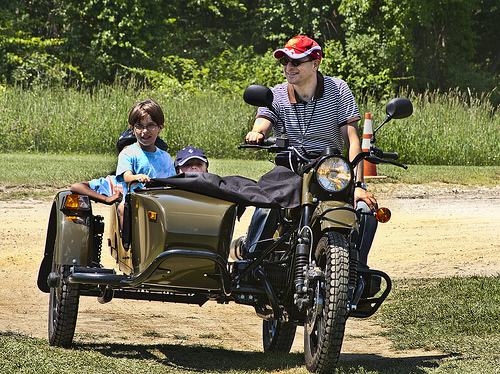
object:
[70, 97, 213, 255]
three children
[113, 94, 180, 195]
boy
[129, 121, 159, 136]
glasses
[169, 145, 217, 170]
cap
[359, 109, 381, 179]
cone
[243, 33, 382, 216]
man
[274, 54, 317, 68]
sunglasses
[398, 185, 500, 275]
road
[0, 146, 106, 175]
grass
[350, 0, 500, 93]
trees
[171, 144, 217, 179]
child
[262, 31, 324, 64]
hat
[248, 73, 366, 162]
shirt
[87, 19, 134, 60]
green leaves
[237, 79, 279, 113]
mirrors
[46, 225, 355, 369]
three tires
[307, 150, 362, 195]
headlight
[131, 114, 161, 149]
face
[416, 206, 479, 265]
dirt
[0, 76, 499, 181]
background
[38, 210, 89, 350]
wheel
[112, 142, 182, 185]
blue shirt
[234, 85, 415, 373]
motorcycle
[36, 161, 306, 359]
sidecar